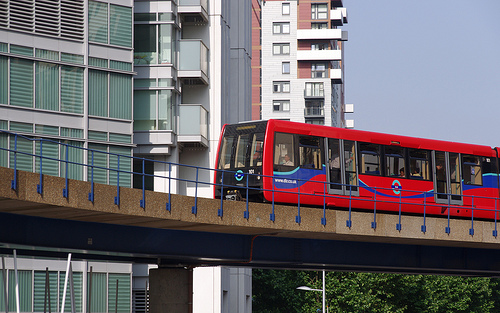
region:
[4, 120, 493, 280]
elevated train in a city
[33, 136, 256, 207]
blue railing on elevated platform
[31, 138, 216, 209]
blue railing on elevated track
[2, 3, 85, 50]
horizontal blinds on windows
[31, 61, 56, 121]
vertical curtains on window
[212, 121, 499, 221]
a red and blue train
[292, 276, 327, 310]
a street light on a pole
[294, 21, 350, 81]
balconies on apartments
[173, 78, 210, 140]
a balcony near the train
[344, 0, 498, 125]
a piece of blue sky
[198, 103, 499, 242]
A red and black colored train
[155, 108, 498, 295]
Train is on a bridge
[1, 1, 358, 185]
Building is in the background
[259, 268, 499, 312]
Trees are in the background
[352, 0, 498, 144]
The sky is clear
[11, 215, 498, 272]
Bottom of the bridge is dark blue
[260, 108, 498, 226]
Side of the train is red in color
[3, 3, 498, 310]
Photo was taken in the daytime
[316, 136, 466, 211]
Two train doors are in view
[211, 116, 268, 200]
Front of the train is black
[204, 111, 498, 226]
Train that is red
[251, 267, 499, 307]
Trees below the train track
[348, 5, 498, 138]
Gray sky beyond the train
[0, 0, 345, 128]
Tall buildings behind the train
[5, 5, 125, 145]
Blinds in the window of building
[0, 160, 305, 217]
Rails along the track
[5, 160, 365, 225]
Rails are blue along the train track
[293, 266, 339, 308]
Street light below train track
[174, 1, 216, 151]
Balconies on the side of building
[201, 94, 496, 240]
Red train on elevated track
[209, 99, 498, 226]
Red passenger train with blue stripes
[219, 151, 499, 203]
Blue stripes on a red train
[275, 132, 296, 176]
Driver of a passenger train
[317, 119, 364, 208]
Doors on a passenger train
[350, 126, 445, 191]
Windows on a passenger train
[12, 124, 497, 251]
Blue railing on a train track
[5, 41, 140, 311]
Large windows on building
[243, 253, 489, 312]
Trees under the train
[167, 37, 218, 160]
Balcony on a tall building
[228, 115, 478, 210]
Blue, Red and Black Metro train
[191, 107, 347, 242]
Commuter train on a track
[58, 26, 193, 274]
High rise building behind railroad track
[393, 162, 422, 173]
Person sitting in a train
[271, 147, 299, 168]
Train operator driving a train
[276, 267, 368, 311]
Street light under a train el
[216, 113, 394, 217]
Train moving on tracks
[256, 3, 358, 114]
White and Red highrise building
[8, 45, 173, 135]
Large glass windows with closed blinds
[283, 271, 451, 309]
Tall trees with green leaves